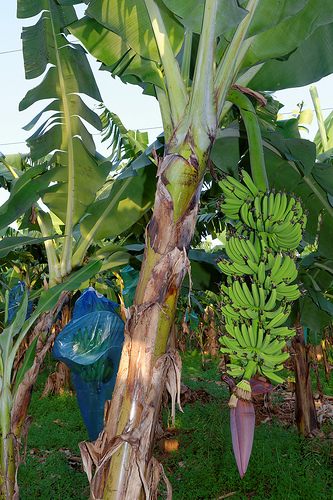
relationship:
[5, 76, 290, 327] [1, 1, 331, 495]
tops of trees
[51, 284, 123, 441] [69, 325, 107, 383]
bag on bananas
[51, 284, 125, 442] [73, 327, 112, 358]
bag on bananas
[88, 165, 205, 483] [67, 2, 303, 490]
trunk of tree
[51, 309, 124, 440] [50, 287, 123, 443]
bananas in plastic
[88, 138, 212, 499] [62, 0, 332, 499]
trunk of banana tree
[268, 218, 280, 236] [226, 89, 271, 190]
banana on branch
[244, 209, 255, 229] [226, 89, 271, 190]
banana on branch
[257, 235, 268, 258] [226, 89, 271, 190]
banana on branch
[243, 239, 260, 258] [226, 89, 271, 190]
banana on branch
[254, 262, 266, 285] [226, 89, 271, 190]
banana on branch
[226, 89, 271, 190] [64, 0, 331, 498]
branch on tree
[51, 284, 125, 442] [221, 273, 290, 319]
bag covering bananas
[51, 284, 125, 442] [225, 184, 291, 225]
bag covering bananas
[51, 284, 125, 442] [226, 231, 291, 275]
bag covering bananas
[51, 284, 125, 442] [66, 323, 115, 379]
bag covering bananas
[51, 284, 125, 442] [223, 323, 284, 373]
bag covering bananas